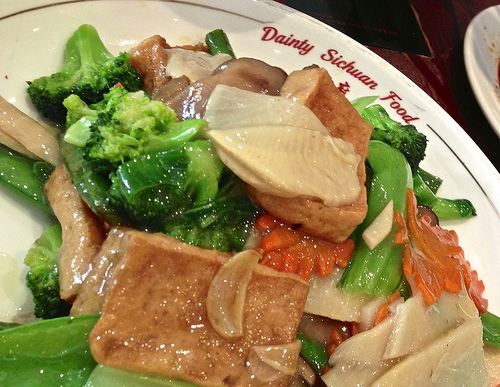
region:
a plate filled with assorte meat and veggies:
[0, 0, 495, 384]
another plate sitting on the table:
[465, 5, 499, 107]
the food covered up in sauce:
[6, 32, 491, 382]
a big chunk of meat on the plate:
[88, 229, 316, 379]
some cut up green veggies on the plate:
[36, 88, 210, 224]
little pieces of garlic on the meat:
[214, 250, 301, 376]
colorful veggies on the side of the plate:
[371, 123, 475, 385]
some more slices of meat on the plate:
[0, 95, 107, 312]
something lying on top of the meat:
[213, 85, 353, 204]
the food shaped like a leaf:
[391, 195, 483, 304]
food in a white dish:
[3, 2, 499, 384]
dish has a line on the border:
[6, 4, 499, 385]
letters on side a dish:
[235, 7, 430, 128]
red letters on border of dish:
[260, 8, 433, 130]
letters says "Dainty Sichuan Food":
[256, 20, 436, 143]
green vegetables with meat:
[1, 26, 495, 385]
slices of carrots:
[386, 190, 487, 315]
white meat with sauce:
[196, 58, 373, 240]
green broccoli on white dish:
[35, 20, 146, 212]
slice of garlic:
[196, 231, 263, 342]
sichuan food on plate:
[18, 31, 499, 372]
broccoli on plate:
[58, 97, 253, 241]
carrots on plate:
[401, 206, 493, 313]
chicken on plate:
[115, 223, 319, 383]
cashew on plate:
[207, 238, 268, 340]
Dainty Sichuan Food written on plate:
[261, 19, 433, 121]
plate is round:
[1, 2, 498, 382]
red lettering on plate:
[265, 16, 430, 126]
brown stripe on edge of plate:
[1, 0, 498, 223]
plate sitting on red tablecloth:
[213, 6, 498, 179]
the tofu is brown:
[287, 60, 375, 224]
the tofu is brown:
[72, 221, 334, 384]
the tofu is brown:
[28, 174, 238, 384]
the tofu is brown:
[196, 58, 427, 312]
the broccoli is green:
[101, 93, 236, 213]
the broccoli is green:
[334, 146, 413, 314]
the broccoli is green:
[9, 28, 204, 226]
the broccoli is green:
[296, 60, 412, 243]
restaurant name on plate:
[253, 17, 421, 127]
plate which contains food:
[1, 2, 498, 384]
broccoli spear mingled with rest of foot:
[82, 84, 210, 164]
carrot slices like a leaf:
[386, 184, 464, 308]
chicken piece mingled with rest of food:
[70, 224, 310, 381]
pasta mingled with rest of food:
[311, 282, 486, 385]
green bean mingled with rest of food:
[343, 132, 411, 304]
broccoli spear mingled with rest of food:
[27, 20, 139, 112]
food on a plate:
[0, 19, 498, 385]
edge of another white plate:
[463, 5, 498, 132]